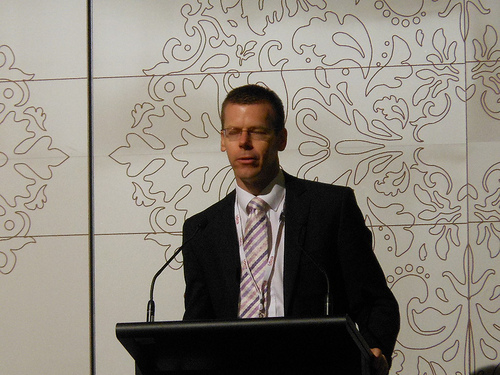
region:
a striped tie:
[244, 194, 273, 317]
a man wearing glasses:
[212, 79, 285, 195]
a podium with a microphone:
[96, 198, 403, 366]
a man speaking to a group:
[171, 84, 406, 356]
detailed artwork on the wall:
[2, 48, 65, 273]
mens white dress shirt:
[232, 178, 289, 315]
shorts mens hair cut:
[214, 81, 292, 159]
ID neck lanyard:
[229, 187, 305, 319]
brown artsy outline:
[109, 113, 170, 188]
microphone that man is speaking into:
[134, 225, 216, 321]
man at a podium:
[178, 74, 403, 371]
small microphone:
[143, 237, 194, 329]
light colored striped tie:
[236, 194, 273, 320]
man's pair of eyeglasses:
[223, 120, 271, 145]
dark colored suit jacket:
[175, 169, 404, 355]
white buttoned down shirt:
[230, 165, 287, 320]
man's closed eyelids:
[228, 129, 267, 136]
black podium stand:
[115, 319, 385, 374]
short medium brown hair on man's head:
[215, 81, 285, 122]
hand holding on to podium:
[368, 343, 396, 368]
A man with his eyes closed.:
[115, 85, 403, 374]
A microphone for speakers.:
[141, 225, 206, 321]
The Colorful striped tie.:
[241, 198, 271, 329]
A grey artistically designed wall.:
[399, 0, 499, 373]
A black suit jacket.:
[181, 171, 401, 321]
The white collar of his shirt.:
[236, 186, 288, 213]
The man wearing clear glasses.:
[215, 125, 282, 140]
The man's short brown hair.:
[220, 83, 281, 100]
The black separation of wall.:
[78, 0, 105, 373]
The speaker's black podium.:
[115, 316, 383, 373]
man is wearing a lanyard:
[210, 121, 309, 325]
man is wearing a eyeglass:
[210, 109, 279, 159]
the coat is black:
[183, 197, 243, 327]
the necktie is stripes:
[238, 200, 278, 317]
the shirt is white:
[220, 193, 299, 345]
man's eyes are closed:
[209, 108, 289, 161]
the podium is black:
[120, 293, 346, 360]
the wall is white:
[59, 34, 145, 207]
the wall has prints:
[194, 29, 485, 89]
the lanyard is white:
[247, 225, 298, 297]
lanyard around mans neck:
[237, 186, 288, 315]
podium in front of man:
[112, 315, 373, 374]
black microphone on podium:
[144, 233, 199, 323]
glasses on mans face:
[223, 124, 279, 142]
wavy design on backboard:
[107, 1, 498, 371]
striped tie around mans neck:
[237, 195, 270, 316]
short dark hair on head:
[217, 81, 282, 136]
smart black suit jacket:
[180, 170, 400, 362]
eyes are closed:
[226, 127, 263, 135]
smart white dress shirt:
[232, 183, 288, 317]